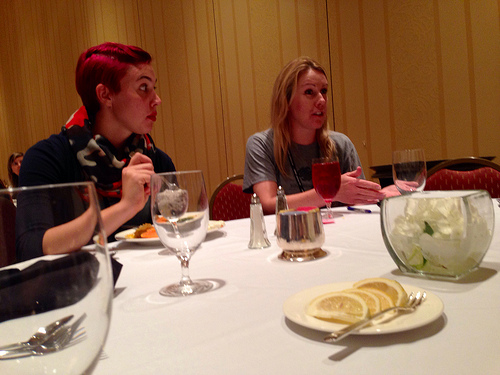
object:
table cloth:
[1, 196, 499, 373]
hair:
[74, 42, 153, 124]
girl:
[242, 56, 402, 214]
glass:
[311, 156, 341, 225]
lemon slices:
[307, 293, 371, 325]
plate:
[285, 282, 445, 336]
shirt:
[241, 128, 369, 210]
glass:
[391, 148, 428, 199]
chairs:
[210, 174, 256, 222]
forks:
[323, 291, 425, 344]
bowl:
[380, 189, 495, 281]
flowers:
[417, 220, 472, 270]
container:
[275, 205, 327, 263]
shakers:
[273, 184, 288, 236]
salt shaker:
[247, 192, 271, 250]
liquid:
[313, 161, 342, 197]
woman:
[15, 41, 180, 259]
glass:
[150, 170, 215, 296]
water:
[153, 217, 206, 251]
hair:
[271, 56, 338, 182]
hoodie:
[16, 105, 178, 262]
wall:
[2, 0, 499, 200]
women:
[7, 150, 25, 198]